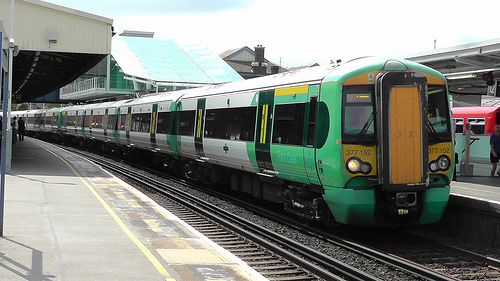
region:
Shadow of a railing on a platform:
[1, 235, 50, 280]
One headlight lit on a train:
[345, 153, 450, 174]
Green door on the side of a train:
[254, 90, 279, 175]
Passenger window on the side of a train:
[201, 105, 257, 142]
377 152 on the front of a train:
[344, 148, 374, 157]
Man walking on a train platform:
[488, 123, 499, 175]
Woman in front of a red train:
[463, 123, 474, 135]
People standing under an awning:
[10, 114, 27, 142]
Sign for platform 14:
[13, 91, 23, 102]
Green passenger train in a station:
[15, 62, 457, 229]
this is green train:
[2, 53, 457, 228]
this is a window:
[342, 81, 451, 145]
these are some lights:
[347, 153, 458, 175]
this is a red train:
[450, 103, 496, 134]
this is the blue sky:
[47, 0, 498, 66]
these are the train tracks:
[40, 132, 498, 279]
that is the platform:
[2, 135, 266, 278]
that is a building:
[219, 49, 289, 79]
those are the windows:
[449, 115, 491, 134]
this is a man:
[484, 120, 499, 180]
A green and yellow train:
[218, 48, 453, 275]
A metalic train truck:
[152, 181, 257, 247]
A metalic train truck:
[270, 214, 329, 278]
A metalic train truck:
[362, 232, 475, 278]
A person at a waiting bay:
[15, 98, 37, 140]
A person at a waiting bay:
[8, 107, 20, 142]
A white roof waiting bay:
[18, 0, 125, 60]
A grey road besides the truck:
[62, 212, 182, 277]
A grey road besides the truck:
[19, 142, 146, 215]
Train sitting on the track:
[202, 58, 399, 265]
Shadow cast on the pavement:
[27, 115, 134, 217]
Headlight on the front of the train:
[342, 144, 375, 181]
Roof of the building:
[129, 28, 212, 100]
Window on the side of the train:
[200, 97, 289, 148]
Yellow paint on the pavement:
[120, 221, 175, 269]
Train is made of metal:
[180, 93, 465, 223]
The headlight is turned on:
[343, 133, 384, 170]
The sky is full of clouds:
[183, 5, 303, 55]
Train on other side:
[462, 93, 499, 145]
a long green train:
[37, 62, 445, 222]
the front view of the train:
[335, 67, 450, 219]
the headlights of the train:
[347, 157, 452, 184]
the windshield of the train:
[422, 81, 446, 139]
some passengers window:
[136, 110, 330, 147]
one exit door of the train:
[253, 91, 270, 167]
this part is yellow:
[388, 90, 421, 187]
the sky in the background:
[225, 7, 370, 39]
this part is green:
[282, 147, 338, 182]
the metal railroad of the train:
[294, 230, 411, 276]